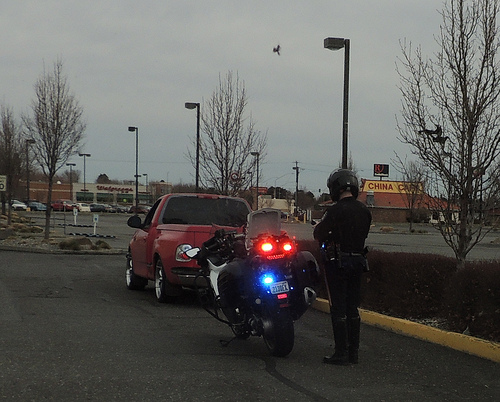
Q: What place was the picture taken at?
A: It was taken at the street.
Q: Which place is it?
A: It is a street.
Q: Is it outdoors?
A: Yes, it is outdoors.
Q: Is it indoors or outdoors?
A: It is outdoors.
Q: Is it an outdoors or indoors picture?
A: It is outdoors.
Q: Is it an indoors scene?
A: No, it is outdoors.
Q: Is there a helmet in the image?
A: Yes, there is a helmet.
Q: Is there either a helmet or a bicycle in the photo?
A: Yes, there is a helmet.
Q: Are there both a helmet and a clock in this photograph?
A: No, there is a helmet but no clocks.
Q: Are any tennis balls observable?
A: No, there are no tennis balls.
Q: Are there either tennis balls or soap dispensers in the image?
A: No, there are no tennis balls or soap dispensers.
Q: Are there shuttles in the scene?
A: No, there are no shuttles.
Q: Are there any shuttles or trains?
A: No, there are no shuttles or trains.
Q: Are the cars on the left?
A: Yes, the cars are on the left of the image.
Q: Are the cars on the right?
A: No, the cars are on the left of the image.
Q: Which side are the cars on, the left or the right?
A: The cars are on the left of the image.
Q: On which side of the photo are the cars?
A: The cars are on the left of the image.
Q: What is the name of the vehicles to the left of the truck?
A: The vehicles are cars.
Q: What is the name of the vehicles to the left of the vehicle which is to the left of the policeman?
A: The vehicles are cars.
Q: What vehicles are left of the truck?
A: The vehicles are cars.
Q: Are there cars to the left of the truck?
A: Yes, there are cars to the left of the truck.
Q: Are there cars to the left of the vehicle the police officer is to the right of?
A: Yes, there are cars to the left of the truck.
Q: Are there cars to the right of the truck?
A: No, the cars are to the left of the truck.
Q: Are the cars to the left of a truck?
A: Yes, the cars are to the left of a truck.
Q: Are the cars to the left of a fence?
A: No, the cars are to the left of a truck.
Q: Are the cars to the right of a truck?
A: No, the cars are to the left of a truck.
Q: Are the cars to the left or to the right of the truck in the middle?
A: The cars are to the left of the truck.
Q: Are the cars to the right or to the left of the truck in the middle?
A: The cars are to the left of the truck.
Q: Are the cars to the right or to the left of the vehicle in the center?
A: The cars are to the left of the truck.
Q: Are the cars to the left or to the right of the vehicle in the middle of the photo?
A: The cars are to the left of the truck.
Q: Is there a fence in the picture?
A: No, there are no fences.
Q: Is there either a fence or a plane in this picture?
A: No, there are no fences or airplanes.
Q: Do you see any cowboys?
A: No, there are no cowboys.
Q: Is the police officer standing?
A: Yes, the police officer is standing.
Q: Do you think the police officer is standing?
A: Yes, the police officer is standing.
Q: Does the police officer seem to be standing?
A: Yes, the police officer is standing.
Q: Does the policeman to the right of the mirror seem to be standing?
A: Yes, the policeman is standing.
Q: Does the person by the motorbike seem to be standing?
A: Yes, the policeman is standing.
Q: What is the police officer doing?
A: The police officer is standing.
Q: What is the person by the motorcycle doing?
A: The police officer is standing.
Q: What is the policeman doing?
A: The police officer is standing.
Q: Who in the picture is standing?
A: The police officer is standing.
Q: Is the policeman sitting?
A: No, the policeman is standing.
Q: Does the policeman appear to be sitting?
A: No, the policeman is standing.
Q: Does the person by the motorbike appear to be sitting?
A: No, the policeman is standing.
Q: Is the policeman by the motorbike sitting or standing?
A: The policeman is standing.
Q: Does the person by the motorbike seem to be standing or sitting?
A: The policeman is standing.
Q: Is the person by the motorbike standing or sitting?
A: The policeman is standing.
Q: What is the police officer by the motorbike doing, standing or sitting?
A: The police officer is standing.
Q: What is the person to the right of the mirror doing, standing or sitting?
A: The police officer is standing.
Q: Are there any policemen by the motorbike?
A: Yes, there is a policeman by the motorbike.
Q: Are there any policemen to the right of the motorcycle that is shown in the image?
A: Yes, there is a policeman to the right of the motorcycle.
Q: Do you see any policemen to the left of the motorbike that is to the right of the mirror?
A: No, the policeman is to the right of the motorcycle.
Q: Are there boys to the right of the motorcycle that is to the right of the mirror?
A: No, there is a policeman to the right of the motorbike.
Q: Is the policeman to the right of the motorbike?
A: Yes, the policeman is to the right of the motorbike.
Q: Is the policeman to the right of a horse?
A: No, the policeman is to the right of the motorbike.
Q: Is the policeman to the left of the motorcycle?
A: No, the policeman is to the right of the motorcycle.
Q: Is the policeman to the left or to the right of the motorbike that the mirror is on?
A: The policeman is to the right of the motorbike.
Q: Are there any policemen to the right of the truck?
A: Yes, there is a policeman to the right of the truck.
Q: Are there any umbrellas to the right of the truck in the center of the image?
A: No, there is a policeman to the right of the truck.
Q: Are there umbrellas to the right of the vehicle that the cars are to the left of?
A: No, there is a policeman to the right of the truck.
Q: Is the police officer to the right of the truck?
A: Yes, the police officer is to the right of the truck.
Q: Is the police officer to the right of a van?
A: No, the police officer is to the right of the truck.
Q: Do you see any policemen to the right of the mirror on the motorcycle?
A: Yes, there is a policeman to the right of the mirror.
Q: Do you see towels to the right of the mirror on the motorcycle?
A: No, there is a policeman to the right of the mirror.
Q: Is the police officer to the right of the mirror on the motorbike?
A: Yes, the police officer is to the right of the mirror.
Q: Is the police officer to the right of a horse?
A: No, the police officer is to the right of the mirror.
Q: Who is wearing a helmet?
A: The policeman is wearing a helmet.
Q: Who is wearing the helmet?
A: The policeman is wearing a helmet.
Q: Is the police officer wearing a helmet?
A: Yes, the police officer is wearing a helmet.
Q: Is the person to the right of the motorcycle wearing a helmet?
A: Yes, the police officer is wearing a helmet.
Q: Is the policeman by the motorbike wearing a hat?
A: No, the police officer is wearing a helmet.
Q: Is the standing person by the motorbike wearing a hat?
A: No, the police officer is wearing a helmet.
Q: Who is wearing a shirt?
A: The policeman is wearing a shirt.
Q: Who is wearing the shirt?
A: The policeman is wearing a shirt.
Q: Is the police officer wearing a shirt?
A: Yes, the police officer is wearing a shirt.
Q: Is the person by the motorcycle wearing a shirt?
A: Yes, the police officer is wearing a shirt.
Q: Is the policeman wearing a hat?
A: No, the policeman is wearing a shirt.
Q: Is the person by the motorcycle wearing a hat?
A: No, the policeman is wearing a shirt.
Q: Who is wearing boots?
A: The police officer is wearing boots.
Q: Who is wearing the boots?
A: The police officer is wearing boots.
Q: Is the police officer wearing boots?
A: Yes, the police officer is wearing boots.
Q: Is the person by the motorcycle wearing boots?
A: Yes, the police officer is wearing boots.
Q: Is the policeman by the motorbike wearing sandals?
A: No, the police officer is wearing boots.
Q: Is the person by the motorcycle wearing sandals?
A: No, the police officer is wearing boots.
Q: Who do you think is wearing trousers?
A: The policeman is wearing trousers.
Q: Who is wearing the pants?
A: The policeman is wearing trousers.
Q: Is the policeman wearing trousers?
A: Yes, the policeman is wearing trousers.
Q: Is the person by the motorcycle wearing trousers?
A: Yes, the policeman is wearing trousers.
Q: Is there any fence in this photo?
A: No, there are no fences.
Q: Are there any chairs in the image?
A: No, there are no chairs.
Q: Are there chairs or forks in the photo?
A: No, there are no chairs or forks.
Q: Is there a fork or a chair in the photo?
A: No, there are no chairs or forks.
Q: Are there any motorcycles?
A: Yes, there is a motorcycle.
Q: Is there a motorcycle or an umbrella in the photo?
A: Yes, there is a motorcycle.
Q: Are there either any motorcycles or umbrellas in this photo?
A: Yes, there is a motorcycle.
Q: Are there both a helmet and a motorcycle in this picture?
A: Yes, there are both a motorcycle and a helmet.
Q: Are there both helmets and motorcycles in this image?
A: Yes, there are both a motorcycle and a helmet.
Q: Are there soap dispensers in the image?
A: No, there are no soap dispensers.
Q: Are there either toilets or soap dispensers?
A: No, there are no soap dispensers or toilets.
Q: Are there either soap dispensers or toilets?
A: No, there are no soap dispensers or toilets.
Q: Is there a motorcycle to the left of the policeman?
A: Yes, there is a motorcycle to the left of the policeman.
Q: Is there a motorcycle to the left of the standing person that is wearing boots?
A: Yes, there is a motorcycle to the left of the policeman.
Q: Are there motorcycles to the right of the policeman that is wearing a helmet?
A: No, the motorcycle is to the left of the police officer.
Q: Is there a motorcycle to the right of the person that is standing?
A: No, the motorcycle is to the left of the police officer.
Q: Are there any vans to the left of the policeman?
A: No, there is a motorcycle to the left of the policeman.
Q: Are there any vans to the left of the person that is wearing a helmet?
A: No, there is a motorcycle to the left of the policeman.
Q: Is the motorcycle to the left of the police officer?
A: Yes, the motorcycle is to the left of the police officer.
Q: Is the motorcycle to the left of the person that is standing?
A: Yes, the motorcycle is to the left of the police officer.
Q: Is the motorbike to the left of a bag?
A: No, the motorbike is to the left of the police officer.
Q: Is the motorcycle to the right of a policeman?
A: No, the motorcycle is to the left of a policeman.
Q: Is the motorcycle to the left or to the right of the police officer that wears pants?
A: The motorcycle is to the left of the policeman.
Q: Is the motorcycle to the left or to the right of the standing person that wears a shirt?
A: The motorcycle is to the left of the policeman.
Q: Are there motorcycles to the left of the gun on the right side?
A: Yes, there is a motorcycle to the left of the gun.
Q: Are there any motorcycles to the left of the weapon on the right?
A: Yes, there is a motorcycle to the left of the gun.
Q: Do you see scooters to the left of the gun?
A: No, there is a motorcycle to the left of the gun.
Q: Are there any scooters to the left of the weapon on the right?
A: No, there is a motorcycle to the left of the gun.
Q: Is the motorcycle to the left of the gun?
A: Yes, the motorcycle is to the left of the gun.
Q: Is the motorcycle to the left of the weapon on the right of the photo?
A: Yes, the motorcycle is to the left of the gun.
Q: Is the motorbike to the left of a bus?
A: No, the motorbike is to the left of the gun.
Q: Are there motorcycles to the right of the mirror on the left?
A: Yes, there is a motorcycle to the right of the mirror.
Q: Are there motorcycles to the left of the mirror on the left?
A: No, the motorcycle is to the right of the mirror.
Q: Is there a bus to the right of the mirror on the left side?
A: No, there is a motorcycle to the right of the mirror.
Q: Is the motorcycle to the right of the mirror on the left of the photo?
A: Yes, the motorcycle is to the right of the mirror.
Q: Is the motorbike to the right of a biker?
A: No, the motorbike is to the right of the mirror.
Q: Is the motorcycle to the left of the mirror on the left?
A: No, the motorcycle is to the right of the mirror.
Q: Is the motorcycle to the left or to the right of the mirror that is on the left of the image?
A: The motorcycle is to the right of the mirror.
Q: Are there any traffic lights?
A: No, there are no traffic lights.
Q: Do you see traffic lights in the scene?
A: No, there are no traffic lights.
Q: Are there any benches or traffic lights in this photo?
A: No, there are no traffic lights or benches.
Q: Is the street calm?
A: Yes, the street is calm.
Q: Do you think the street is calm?
A: Yes, the street is calm.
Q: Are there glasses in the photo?
A: No, there are no glasses.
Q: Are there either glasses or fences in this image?
A: No, there are no glasses or fences.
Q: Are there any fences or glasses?
A: No, there are no glasses or fences.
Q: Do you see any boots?
A: Yes, there are boots.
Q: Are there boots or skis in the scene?
A: Yes, there are boots.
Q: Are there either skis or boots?
A: Yes, there are boots.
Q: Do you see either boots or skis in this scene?
A: Yes, there are boots.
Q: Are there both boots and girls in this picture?
A: No, there are boots but no girls.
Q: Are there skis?
A: No, there are no skis.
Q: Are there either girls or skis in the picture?
A: No, there are no skis or girls.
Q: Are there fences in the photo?
A: No, there are no fences.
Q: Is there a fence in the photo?
A: No, there are no fences.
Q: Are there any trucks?
A: Yes, there is a truck.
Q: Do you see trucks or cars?
A: Yes, there is a truck.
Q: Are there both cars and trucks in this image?
A: Yes, there are both a truck and a car.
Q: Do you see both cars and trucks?
A: Yes, there are both a truck and a car.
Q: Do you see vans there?
A: No, there are no vans.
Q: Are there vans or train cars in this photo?
A: No, there are no vans or train cars.